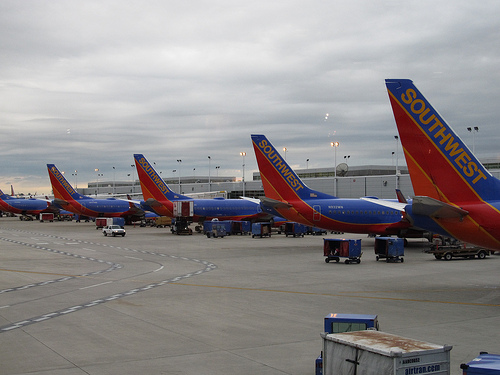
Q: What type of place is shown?
A: It is an airport.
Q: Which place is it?
A: It is an airport.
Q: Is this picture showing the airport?
A: Yes, it is showing the airport.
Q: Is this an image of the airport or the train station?
A: It is showing the airport.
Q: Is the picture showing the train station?
A: No, the picture is showing the airport.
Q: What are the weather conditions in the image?
A: It is cloudy.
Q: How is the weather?
A: It is cloudy.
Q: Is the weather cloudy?
A: Yes, it is cloudy.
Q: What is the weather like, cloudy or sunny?
A: It is cloudy.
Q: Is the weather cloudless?
A: No, it is cloudy.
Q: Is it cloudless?
A: No, it is cloudy.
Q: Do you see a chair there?
A: No, there are no chairs.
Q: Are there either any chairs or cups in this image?
A: No, there are no chairs or cups.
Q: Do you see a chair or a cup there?
A: No, there are no chairs or cups.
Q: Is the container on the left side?
A: No, the container is on the right of the image.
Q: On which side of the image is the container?
A: The container is on the right of the image.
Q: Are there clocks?
A: No, there are no clocks.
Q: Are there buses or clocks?
A: No, there are no clocks or buses.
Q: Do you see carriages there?
A: No, there are no carriages.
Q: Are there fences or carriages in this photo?
A: No, there are no carriages or fences.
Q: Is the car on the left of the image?
A: Yes, the car is on the left of the image.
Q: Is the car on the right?
A: No, the car is on the left of the image.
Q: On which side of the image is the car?
A: The car is on the left of the image.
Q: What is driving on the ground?
A: The car is driving on the ground.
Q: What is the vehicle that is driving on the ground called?
A: The vehicle is a car.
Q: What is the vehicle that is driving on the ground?
A: The vehicle is a car.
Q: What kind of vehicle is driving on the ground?
A: The vehicle is a car.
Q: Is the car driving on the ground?
A: Yes, the car is driving on the ground.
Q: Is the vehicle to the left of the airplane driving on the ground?
A: Yes, the car is driving on the ground.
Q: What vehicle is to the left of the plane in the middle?
A: The vehicle is a car.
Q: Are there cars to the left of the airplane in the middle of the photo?
A: Yes, there is a car to the left of the plane.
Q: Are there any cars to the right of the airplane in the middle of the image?
A: No, the car is to the left of the plane.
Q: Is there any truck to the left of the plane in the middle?
A: No, there is a car to the left of the airplane.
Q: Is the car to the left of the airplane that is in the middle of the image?
A: Yes, the car is to the left of the airplane.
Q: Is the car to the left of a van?
A: No, the car is to the left of the airplane.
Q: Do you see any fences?
A: No, there are no fences.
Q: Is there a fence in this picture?
A: No, there are no fences.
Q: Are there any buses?
A: No, there are no buses.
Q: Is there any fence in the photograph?
A: No, there are no fences.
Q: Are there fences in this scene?
A: No, there are no fences.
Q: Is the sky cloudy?
A: Yes, the sky is cloudy.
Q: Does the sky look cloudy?
A: Yes, the sky is cloudy.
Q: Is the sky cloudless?
A: No, the sky is cloudy.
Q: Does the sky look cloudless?
A: No, the sky is cloudy.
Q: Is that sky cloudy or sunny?
A: The sky is cloudy.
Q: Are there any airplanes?
A: Yes, there is an airplane.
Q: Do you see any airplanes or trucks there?
A: Yes, there is an airplane.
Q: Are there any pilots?
A: No, there are no pilots.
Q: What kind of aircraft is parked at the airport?
A: The aircraft is an airplane.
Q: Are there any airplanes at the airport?
A: Yes, there is an airplane at the airport.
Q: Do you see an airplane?
A: Yes, there is an airplane.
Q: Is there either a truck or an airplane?
A: Yes, there is an airplane.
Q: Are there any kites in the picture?
A: No, there are no kites.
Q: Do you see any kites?
A: No, there are no kites.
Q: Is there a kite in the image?
A: No, there are no kites.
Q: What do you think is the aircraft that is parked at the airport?
A: The aircraft is an airplane.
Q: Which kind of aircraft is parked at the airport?
A: The aircraft is an airplane.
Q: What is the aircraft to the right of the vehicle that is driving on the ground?
A: The aircraft is an airplane.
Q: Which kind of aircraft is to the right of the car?
A: The aircraft is an airplane.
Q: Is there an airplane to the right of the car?
A: Yes, there is an airplane to the right of the car.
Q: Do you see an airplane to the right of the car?
A: Yes, there is an airplane to the right of the car.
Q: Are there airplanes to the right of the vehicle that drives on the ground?
A: Yes, there is an airplane to the right of the car.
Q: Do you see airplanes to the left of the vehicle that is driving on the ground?
A: No, the airplane is to the right of the car.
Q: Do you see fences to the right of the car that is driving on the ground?
A: No, there is an airplane to the right of the car.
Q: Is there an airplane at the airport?
A: Yes, there is an airplane at the airport.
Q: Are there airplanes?
A: Yes, there is an airplane.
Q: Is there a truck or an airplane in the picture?
A: Yes, there is an airplane.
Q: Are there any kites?
A: No, there are no kites.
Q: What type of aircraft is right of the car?
A: The aircraft is an airplane.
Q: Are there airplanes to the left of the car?
A: No, the airplane is to the right of the car.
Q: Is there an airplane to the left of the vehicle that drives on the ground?
A: No, the airplane is to the right of the car.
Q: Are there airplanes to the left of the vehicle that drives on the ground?
A: No, the airplane is to the right of the car.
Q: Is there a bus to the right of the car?
A: No, there is an airplane to the right of the car.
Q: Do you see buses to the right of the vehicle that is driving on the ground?
A: No, there is an airplane to the right of the car.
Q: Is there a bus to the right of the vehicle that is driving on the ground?
A: No, there is an airplane to the right of the car.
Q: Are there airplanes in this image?
A: Yes, there is an airplane.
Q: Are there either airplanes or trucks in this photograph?
A: Yes, there is an airplane.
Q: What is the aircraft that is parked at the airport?
A: The aircraft is an airplane.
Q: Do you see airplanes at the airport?
A: Yes, there is an airplane at the airport.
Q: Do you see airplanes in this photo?
A: Yes, there is an airplane.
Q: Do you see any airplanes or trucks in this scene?
A: Yes, there is an airplane.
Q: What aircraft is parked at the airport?
A: The aircraft is an airplane.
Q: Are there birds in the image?
A: No, there are no birds.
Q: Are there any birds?
A: No, there are no birds.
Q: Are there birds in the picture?
A: No, there are no birds.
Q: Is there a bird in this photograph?
A: No, there are no birds.